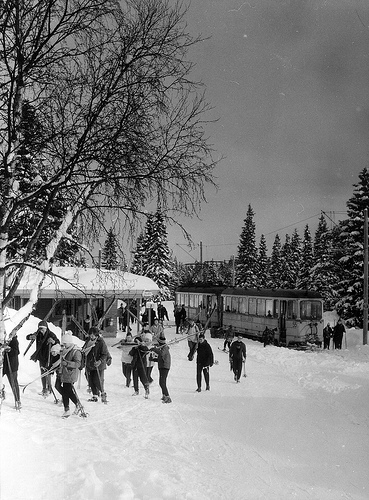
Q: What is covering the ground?
A: Snow.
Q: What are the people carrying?
A: Skis.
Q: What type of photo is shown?
A: Black and white.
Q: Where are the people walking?
A: Uphill.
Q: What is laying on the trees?
A: Snow.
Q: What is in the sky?
A: Clouds.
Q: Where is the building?
A: Behind the people.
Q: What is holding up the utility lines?
A: Poles.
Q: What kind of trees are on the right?
A: Pine trees.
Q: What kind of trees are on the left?
A: Deciduous trees.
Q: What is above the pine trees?
A: Wires.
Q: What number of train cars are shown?
A: Two.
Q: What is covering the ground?
A: Snow.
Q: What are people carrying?
A: Skis.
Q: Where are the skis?
A: In people's arms.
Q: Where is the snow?
A: On the ground.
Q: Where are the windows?
A: On the train.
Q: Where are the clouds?
A: In the sky.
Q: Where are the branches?
A: In the tree.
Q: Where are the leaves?
A: In the trees.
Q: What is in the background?
A: Trees.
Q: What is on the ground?
A: Snow.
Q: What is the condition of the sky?
A: Clear.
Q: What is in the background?
A: A building.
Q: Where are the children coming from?
A: A bus.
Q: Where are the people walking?
A: To the ski hill.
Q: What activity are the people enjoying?
A: Skiing.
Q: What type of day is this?
A: Snowy.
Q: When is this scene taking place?
A: Day time.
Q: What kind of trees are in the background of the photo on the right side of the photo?
A: Evergreen trees.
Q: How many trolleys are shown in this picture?
A: One.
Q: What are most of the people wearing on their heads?
A: Hats.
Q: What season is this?
A: Winter.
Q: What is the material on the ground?
A: Snow.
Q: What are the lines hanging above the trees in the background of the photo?
A: Power lines.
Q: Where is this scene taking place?
A: In the snow.